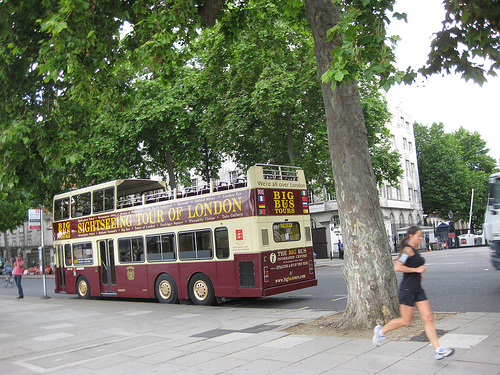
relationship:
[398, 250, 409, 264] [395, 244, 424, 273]
band on arm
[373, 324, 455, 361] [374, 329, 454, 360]
shoes on feet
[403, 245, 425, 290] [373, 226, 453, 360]
top on girl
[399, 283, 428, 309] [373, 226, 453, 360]
shorts on girl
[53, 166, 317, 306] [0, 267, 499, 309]
bus on road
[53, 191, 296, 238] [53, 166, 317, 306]
writing on bus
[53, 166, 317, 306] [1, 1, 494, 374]
bus touring london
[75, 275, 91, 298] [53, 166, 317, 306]
wheel of bus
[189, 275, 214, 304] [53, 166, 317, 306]
wheel of bus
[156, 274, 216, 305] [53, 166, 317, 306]
wheels of bus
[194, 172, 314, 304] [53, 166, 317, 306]
back of bus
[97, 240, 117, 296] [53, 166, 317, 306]
door of bus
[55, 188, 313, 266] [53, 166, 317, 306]
windows of bus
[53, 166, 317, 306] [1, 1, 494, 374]
bus sightseeing london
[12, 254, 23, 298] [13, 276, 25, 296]
woman in jeans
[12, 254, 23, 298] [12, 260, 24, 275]
woman in shirt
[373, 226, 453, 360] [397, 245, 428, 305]
woman wearing clothing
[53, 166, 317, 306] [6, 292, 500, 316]
bus at curbside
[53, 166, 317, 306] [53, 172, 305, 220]
bus has deck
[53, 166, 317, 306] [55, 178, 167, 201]
bus has roof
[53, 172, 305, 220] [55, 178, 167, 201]
deck has roof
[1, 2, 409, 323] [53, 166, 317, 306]
trees around bus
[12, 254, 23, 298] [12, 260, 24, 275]
pedestrian wearing top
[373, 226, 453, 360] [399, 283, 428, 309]
jogger wearing shorts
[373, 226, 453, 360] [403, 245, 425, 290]
jogger wearing top